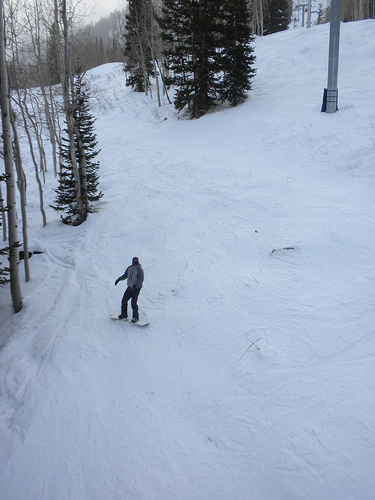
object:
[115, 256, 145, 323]
man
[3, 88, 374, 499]
snow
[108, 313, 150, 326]
board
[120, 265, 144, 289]
jacket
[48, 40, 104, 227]
trees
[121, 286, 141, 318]
pants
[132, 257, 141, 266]
hat